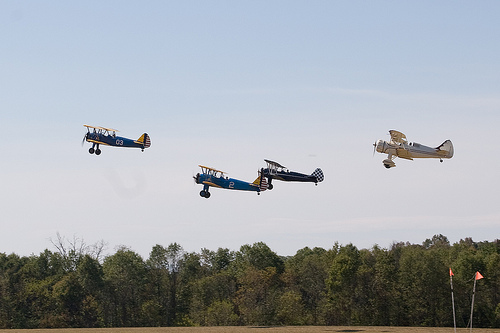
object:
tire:
[200, 191, 206, 198]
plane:
[257, 159, 325, 190]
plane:
[371, 130, 455, 169]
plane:
[83, 124, 151, 155]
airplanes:
[193, 164, 269, 198]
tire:
[384, 165, 391, 169]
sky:
[0, 0, 500, 259]